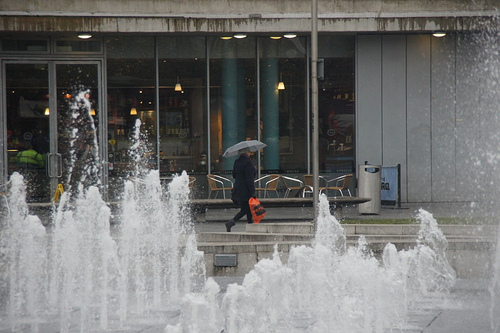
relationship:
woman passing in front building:
[224, 139, 261, 232] [0, 1, 495, 219]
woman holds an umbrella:
[224, 139, 261, 232] [221, 133, 267, 159]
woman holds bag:
[224, 139, 261, 232] [248, 192, 265, 225]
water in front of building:
[0, 0, 499, 333] [0, 1, 495, 219]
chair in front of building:
[321, 169, 354, 204] [0, 1, 495, 219]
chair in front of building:
[301, 171, 328, 201] [0, 1, 495, 219]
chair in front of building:
[278, 171, 304, 200] [0, 1, 495, 219]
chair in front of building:
[248, 167, 281, 202] [0, 1, 495, 219]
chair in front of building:
[203, 171, 235, 200] [0, 1, 495, 219]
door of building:
[1, 56, 107, 210] [0, 1, 495, 219]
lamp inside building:
[275, 71, 287, 92] [0, 1, 495, 219]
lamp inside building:
[173, 76, 184, 95] [0, 1, 495, 219]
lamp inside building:
[129, 103, 138, 118] [0, 1, 495, 219]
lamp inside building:
[85, 103, 97, 118] [0, 1, 495, 219]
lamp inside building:
[42, 104, 54, 116] [0, 1, 495, 219]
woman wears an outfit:
[224, 139, 261, 232] [231, 155, 256, 224]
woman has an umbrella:
[224, 139, 261, 232] [221, 133, 267, 159]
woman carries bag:
[224, 139, 261, 232] [248, 192, 265, 225]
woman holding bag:
[224, 139, 261, 232] [248, 192, 265, 225]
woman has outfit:
[224, 139, 261, 232] [231, 155, 256, 224]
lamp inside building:
[91, 104, 96, 115] [0, 1, 495, 219]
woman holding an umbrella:
[224, 139, 261, 232] [221, 133, 267, 159]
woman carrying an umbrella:
[224, 139, 261, 232] [221, 133, 267, 159]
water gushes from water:
[0, 87, 458, 305] [0, 0, 499, 333]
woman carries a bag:
[224, 139, 261, 232] [248, 192, 265, 225]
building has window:
[0, 1, 495, 219] [104, 33, 160, 202]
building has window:
[0, 1, 495, 219] [156, 30, 210, 201]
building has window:
[0, 1, 495, 219] [207, 31, 258, 200]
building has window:
[0, 1, 495, 219] [258, 35, 309, 195]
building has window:
[0, 1, 495, 219] [308, 31, 356, 202]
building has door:
[0, 1, 495, 219] [1, 56, 107, 210]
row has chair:
[134, 170, 362, 208] [321, 169, 354, 204]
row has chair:
[134, 170, 362, 208] [301, 171, 328, 201]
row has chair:
[134, 170, 362, 208] [278, 171, 304, 200]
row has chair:
[134, 170, 362, 208] [248, 167, 281, 202]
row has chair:
[134, 170, 362, 208] [203, 171, 235, 200]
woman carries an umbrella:
[224, 139, 261, 232] [221, 133, 267, 159]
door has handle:
[1, 56, 107, 210] [55, 152, 63, 181]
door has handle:
[1, 56, 107, 210] [44, 150, 55, 183]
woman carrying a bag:
[224, 139, 261, 232] [248, 192, 265, 225]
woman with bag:
[224, 139, 261, 232] [248, 192, 265, 225]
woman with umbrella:
[224, 139, 261, 232] [221, 133, 267, 159]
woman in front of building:
[224, 139, 261, 232] [0, 1, 495, 219]